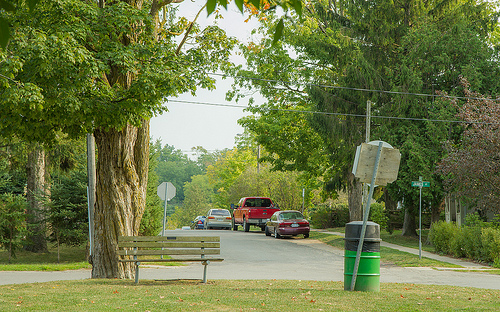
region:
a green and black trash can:
[345, 220, 380, 295]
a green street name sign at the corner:
[410, 173, 430, 254]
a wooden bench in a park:
[118, 232, 223, 277]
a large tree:
[98, 56, 148, 288]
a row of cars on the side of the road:
[193, 191, 310, 246]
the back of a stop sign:
[158, 179, 177, 201]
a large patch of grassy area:
[45, 275, 341, 310]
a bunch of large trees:
[345, 21, 498, 227]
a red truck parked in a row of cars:
[233, 191, 273, 234]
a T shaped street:
[65, 243, 468, 281]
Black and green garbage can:
[342, 218, 379, 291]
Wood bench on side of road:
[107, 231, 224, 282]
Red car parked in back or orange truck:
[257, 204, 312, 237]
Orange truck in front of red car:
[231, 190, 278, 231]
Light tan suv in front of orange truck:
[191, 206, 233, 226]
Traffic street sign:
[349, 138, 402, 310]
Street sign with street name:
[407, 174, 429, 244]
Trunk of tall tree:
[95, 65, 159, 285]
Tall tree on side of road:
[2, 1, 246, 283]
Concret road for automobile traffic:
[4, 223, 496, 290]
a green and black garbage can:
[328, 192, 435, 302]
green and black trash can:
[325, 200, 396, 285]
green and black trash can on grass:
[307, 212, 414, 309]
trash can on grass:
[328, 202, 397, 310]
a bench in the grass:
[97, 195, 274, 307]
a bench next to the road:
[100, 203, 264, 310]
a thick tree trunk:
[79, 123, 160, 220]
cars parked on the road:
[198, 167, 331, 259]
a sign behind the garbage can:
[339, 116, 434, 303]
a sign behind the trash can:
[304, 104, 433, 281]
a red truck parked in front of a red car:
[225, 168, 279, 233]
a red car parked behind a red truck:
[262, 203, 314, 238]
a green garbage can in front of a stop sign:
[338, 213, 385, 288]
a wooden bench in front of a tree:
[109, 230, 239, 278]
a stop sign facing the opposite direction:
[154, 177, 179, 207]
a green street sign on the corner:
[405, 167, 434, 207]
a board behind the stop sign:
[354, 140, 403, 182]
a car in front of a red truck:
[203, 204, 237, 231]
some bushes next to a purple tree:
[430, 216, 496, 264]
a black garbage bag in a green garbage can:
[342, 231, 384, 256]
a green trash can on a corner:
[345, 222, 391, 288]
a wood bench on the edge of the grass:
[103, 221, 233, 289]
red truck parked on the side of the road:
[226, 189, 273, 230]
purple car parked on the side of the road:
[262, 208, 318, 245]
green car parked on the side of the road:
[203, 205, 233, 228]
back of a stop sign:
[150, 174, 181, 235]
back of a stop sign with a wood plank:
[351, 140, 403, 197]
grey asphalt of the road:
[216, 241, 324, 276]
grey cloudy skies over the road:
[160, 103, 236, 136]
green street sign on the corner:
[403, 173, 438, 249]